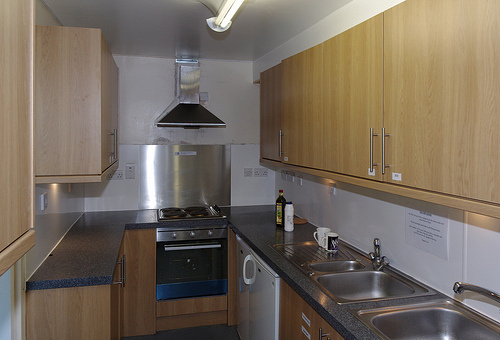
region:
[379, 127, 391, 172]
silver handle on cupboard.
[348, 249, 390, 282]
faucet on the sink.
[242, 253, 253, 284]
handle on the dishwasher.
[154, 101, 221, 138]
vent above the stove.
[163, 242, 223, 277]
door of the oven.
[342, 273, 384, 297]
stainless steel sink on counter.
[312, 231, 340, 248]
mug on the counter.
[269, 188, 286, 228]
bottle on the counter.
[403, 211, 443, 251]
writing on piece of paper.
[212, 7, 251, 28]
light on the ceiling.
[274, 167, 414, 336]
the sink is silver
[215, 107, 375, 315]
the sink is silver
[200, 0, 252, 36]
A light fixture on the ceiling.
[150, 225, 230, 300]
A small oven.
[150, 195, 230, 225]
A small stove.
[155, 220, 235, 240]
The control panel for the oven and stove.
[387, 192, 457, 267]
A piece of paper is attached to the wall.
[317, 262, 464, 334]
Two sinks.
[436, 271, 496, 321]
A faucet.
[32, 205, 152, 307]
A kitchen counter.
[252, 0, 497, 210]
Cabinets with metal handles.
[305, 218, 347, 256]
Two coffee mugs.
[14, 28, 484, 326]
A kitchen scene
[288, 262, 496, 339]
A kitchen sink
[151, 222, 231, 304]
This is an oven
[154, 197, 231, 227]
The stove top has four burners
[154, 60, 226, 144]
This is an exhaust hood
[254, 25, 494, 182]
These are kitchen cabinets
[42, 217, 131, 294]
A counter top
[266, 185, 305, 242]
Bottles are on the counter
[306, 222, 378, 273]
Two mugs are beside the sink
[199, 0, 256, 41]
A light is on the ceiling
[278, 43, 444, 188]
brown kitchen cabinets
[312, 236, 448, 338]
silver kitchen sink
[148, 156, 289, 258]
combination stove and oven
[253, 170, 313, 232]
kitchen spices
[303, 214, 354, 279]
two empty coffee cups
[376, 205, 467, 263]
note on wall of kitchen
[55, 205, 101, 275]
ceramic blue counter top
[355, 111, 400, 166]
handle to kitchen cabinets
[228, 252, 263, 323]
door to dish washing machine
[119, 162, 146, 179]
power outlet on kitchen wall